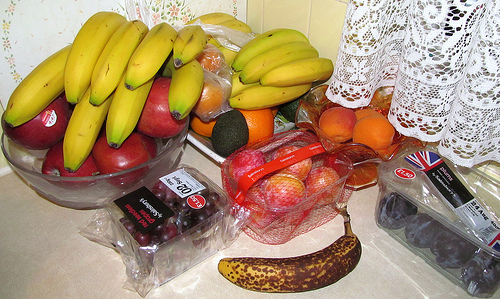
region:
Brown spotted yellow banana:
[217, 203, 361, 291]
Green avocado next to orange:
[208, 109, 246, 156]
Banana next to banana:
[258, 56, 335, 86]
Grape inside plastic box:
[157, 221, 177, 240]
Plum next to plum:
[378, 190, 416, 227]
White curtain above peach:
[323, 0, 498, 168]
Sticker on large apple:
[38, 107, 57, 127]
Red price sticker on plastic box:
[185, 190, 205, 210]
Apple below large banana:
[93, 133, 155, 189]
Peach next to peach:
[318, 106, 355, 141]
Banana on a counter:
[213, 202, 363, 294]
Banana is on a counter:
[210, 199, 366, 295]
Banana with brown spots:
[208, 202, 367, 296]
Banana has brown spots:
[212, 200, 363, 294]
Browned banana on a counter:
[209, 200, 366, 297]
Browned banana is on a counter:
[215, 203, 363, 293]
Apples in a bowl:
[1, 66, 185, 176]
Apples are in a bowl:
[1, 71, 190, 186]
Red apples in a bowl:
[1, 67, 192, 184]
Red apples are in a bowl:
[1, 74, 188, 184]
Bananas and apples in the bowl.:
[17, 29, 339, 280]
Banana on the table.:
[206, 209, 386, 297]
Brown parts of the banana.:
[183, 208, 296, 285]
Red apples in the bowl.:
[3, 50, 231, 246]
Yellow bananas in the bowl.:
[26, 7, 206, 146]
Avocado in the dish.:
[206, 97, 281, 170]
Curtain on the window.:
[336, 11, 495, 159]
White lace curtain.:
[327, 16, 451, 92]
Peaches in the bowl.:
[274, 49, 424, 206]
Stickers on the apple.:
[25, 90, 101, 150]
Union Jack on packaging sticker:
[404, 134, 499, 250]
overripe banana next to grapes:
[219, 195, 359, 296]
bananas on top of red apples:
[3, 13, 203, 175]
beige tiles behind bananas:
[251, 3, 358, 97]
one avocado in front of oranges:
[213, 100, 249, 163]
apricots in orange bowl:
[296, 87, 421, 188]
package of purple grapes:
[97, 163, 237, 288]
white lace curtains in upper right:
[322, 0, 497, 172]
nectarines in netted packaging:
[218, 121, 355, 242]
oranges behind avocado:
[190, 89, 280, 149]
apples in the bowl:
[39, 78, 174, 209]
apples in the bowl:
[7, 48, 201, 250]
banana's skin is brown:
[194, 212, 378, 294]